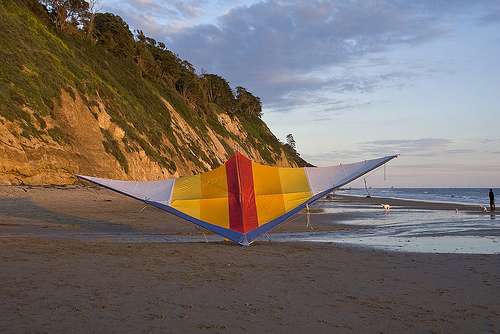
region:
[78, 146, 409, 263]
this is a kite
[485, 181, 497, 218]
this is a person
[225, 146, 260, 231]
a red part of a kite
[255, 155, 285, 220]
a yellow part of a kite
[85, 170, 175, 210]
a grey part of the kite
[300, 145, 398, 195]
a grey part of the kite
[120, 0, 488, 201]
the sky is clear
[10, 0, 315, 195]
this is a big rock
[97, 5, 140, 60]
a bush of trees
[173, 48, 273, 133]
a bush of trees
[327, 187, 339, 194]
tip of a kite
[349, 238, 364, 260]
part of a beach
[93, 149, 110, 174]
part of a landscape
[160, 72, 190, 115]
part of a forest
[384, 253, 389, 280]
part of a shore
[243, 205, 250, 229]
front of a kite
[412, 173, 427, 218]
part of an ocean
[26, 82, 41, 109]
part of the grass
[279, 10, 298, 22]
part of the cloud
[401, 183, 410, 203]
part of the horizon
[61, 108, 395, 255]
Hang glider on ground.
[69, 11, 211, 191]
Mountain in the background.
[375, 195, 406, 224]
White dog on the beach.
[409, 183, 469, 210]
Blue water in the background.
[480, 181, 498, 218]
Person standing on the beach.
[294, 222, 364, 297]
Wet beach sand on the ground.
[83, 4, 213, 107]
Trees on the top of the mountain.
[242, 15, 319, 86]
Gray clouds in the sky.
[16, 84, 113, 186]
Brown rock on the side of the mountain.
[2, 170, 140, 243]
Shadow from hanglider on the sand.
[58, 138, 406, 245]
Hang glider on the ground.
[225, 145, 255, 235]
Red strip on the hang glider.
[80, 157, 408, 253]
The hang glider is pointing downward.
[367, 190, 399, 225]
Dog in the background.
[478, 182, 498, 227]
Person walking a dog.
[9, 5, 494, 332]
Taken on a beach.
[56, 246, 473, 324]
The sand is dark.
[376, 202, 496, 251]
Water on the sand.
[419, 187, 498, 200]
The water is blue.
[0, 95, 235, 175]
Dirt showing on the hill.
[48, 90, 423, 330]
Someone hang gliding on a beach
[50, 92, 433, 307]
Hang glider is resting on a beach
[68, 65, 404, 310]
A hang glider has landed on a beach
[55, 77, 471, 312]
A hang glider is close to the ocean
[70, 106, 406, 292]
The hang glider is brightly colored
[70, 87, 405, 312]
A glider has just landed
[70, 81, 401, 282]
A canvas glider resting in the sand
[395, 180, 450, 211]
Waves coming in to a seashore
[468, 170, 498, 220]
People are on a seashore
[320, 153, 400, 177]
Wing of a hang glider